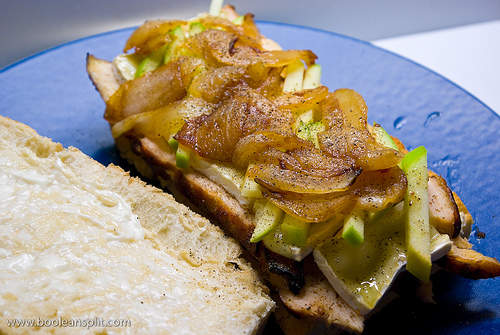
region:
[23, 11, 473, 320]
lunch entree on blue plate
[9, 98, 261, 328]
bread with butter spread on it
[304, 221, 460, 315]
soft white cheese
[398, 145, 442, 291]
fresh apple slices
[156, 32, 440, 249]
food sprinkled with pepper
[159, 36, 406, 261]
food with spices sprinkled on top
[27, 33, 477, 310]
one roll sliced into two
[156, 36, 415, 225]
cooked onions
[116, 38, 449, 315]
cheese, apple, and onions on bread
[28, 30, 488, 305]
food on opaque blue plate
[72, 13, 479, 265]
Food item covered in cooked veggies.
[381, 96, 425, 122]
section of a wet blue plate.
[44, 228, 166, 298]
bread sitting next to another food item.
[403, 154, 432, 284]
grilled green pepper.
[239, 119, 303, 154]
grilled onions on a food item.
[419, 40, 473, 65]
object that blue plate of food is sitting on.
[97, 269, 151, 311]
food item covered a slice of bread.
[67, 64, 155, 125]
a piece of bread covered in vegetables.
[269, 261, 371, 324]
section of bread covered in greasy grilled items.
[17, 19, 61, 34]
the ground near a plate of food.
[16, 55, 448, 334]
Bread sandwich is on plate.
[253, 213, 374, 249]
Avocado is top of bread.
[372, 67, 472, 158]
Plate is blue color.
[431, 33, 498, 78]
Table is white color.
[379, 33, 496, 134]
plate is on the table.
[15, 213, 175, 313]
Cheese is spread on bread.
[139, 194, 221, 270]
Bread is brown color.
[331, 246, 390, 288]
Sauce is green color.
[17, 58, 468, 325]
One plate of food is on table.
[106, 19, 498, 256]
bread with onions on it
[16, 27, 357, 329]
sandwich on blue plate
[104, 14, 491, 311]
fried onions on sandwhich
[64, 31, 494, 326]
blue plate on white table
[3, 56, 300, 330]
one piece of bread with nothing on it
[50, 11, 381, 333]
sandwich not put together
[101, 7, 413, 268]
fried onions on top of green vegetable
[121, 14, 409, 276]
vegetables on bread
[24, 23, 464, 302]
bread with green and brown and white veggies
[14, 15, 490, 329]
The plate is blue.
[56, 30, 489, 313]
Food is sitting on the plate.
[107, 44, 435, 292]
Vegetables on the sandwich.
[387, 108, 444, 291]
Green apple slices.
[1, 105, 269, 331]
Bread is toasted.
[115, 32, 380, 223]
Onions are caramelized.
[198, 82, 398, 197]
Onions are brown.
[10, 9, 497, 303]
Plate is sitting on the table.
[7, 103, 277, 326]
The crust is brown.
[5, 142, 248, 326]
Cheese is melted on the bun.